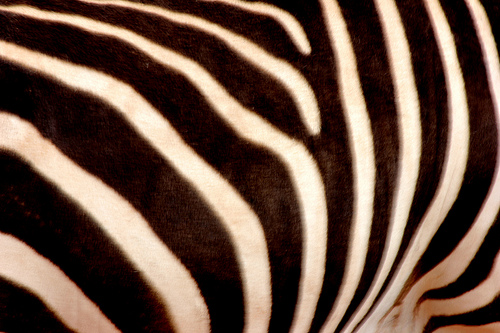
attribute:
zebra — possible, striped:
[0, 1, 499, 332]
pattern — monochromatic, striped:
[1, 2, 499, 333]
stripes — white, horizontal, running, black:
[2, 2, 499, 331]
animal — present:
[2, 2, 499, 331]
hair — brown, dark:
[4, 15, 255, 177]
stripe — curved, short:
[207, 2, 313, 57]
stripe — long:
[0, 39, 274, 333]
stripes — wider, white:
[2, 3, 330, 332]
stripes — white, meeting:
[317, 135, 499, 332]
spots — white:
[4, 186, 62, 236]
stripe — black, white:
[411, 2, 499, 303]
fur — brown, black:
[1, 278, 65, 332]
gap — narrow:
[352, 228, 419, 331]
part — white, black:
[411, 183, 499, 331]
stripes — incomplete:
[147, 1, 324, 139]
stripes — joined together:
[360, 287, 436, 332]